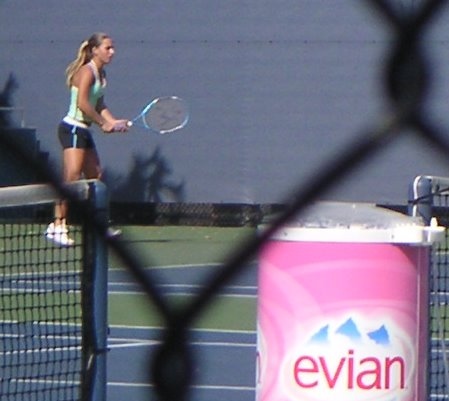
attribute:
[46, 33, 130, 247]
person — playing tennis, holding, playing, preparing, blonde, woman, player, blond, tennis player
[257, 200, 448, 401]
container — pink, water cooler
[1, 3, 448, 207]
wall — blue, gray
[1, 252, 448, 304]
court — blue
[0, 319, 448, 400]
court — blue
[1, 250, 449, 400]
courts — surrounded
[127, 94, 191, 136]
racket — blue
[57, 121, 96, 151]
shorts — navy blue, black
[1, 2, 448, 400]
fence — wire, chain link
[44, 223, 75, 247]
shoe — white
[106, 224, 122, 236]
shoe — white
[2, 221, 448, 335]
surround — green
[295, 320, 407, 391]
logo — evian